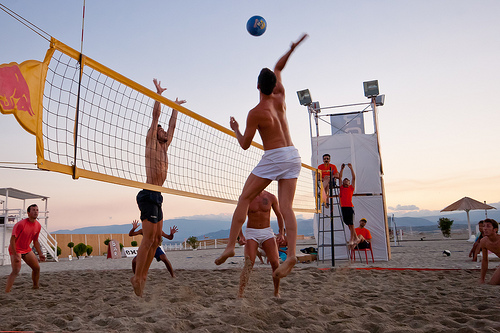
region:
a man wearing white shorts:
[204, 36, 313, 281]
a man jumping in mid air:
[207, 33, 309, 279]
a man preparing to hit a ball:
[202, 12, 316, 282]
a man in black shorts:
[116, 65, 183, 300]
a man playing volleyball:
[126, 69, 188, 300]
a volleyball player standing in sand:
[4, 199, 50, 300]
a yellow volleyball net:
[1, 16, 330, 225]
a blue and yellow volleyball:
[238, 13, 268, 41]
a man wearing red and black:
[334, 157, 359, 243]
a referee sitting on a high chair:
[310, 152, 352, 267]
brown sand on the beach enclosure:
[118, 287, 325, 324]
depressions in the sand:
[316, 278, 401, 320]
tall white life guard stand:
[290, 64, 395, 258]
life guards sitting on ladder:
[302, 141, 364, 218]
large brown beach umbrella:
[443, 189, 490, 233]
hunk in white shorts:
[223, 216, 284, 259]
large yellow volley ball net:
[17, 28, 295, 218]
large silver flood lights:
[290, 78, 397, 125]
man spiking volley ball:
[217, 14, 319, 82]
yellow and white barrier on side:
[50, 223, 217, 264]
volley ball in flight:
[233, 11, 273, 42]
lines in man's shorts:
[244, 155, 302, 194]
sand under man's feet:
[270, 254, 310, 286]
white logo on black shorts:
[138, 214, 168, 221]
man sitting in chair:
[343, 215, 403, 269]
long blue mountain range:
[99, 203, 236, 254]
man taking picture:
[334, 150, 388, 223]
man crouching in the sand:
[5, 197, 55, 273]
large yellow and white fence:
[62, 220, 156, 257]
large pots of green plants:
[66, 233, 106, 264]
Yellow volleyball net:
[30, 28, 323, 216]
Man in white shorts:
[215, 29, 311, 276]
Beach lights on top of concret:
[294, 76, 386, 137]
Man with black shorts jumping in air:
[125, 80, 185, 300]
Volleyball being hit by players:
[241, 13, 267, 35]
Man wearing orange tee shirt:
[6, 201, 46, 282]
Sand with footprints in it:
[3, 270, 494, 327]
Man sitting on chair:
[311, 150, 341, 205]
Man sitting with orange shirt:
[345, 216, 371, 259]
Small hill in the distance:
[435, 191, 497, 212]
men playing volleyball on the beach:
[18, 31, 337, 298]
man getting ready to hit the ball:
[216, 40, 316, 275]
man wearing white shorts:
[235, 168, 295, 305]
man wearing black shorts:
[126, 57, 186, 300]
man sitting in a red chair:
[347, 207, 387, 274]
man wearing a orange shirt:
[331, 152, 363, 242]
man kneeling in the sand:
[473, 212, 497, 288]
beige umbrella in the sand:
[440, 182, 487, 259]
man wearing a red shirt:
[5, 191, 65, 294]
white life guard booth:
[2, 176, 69, 275]